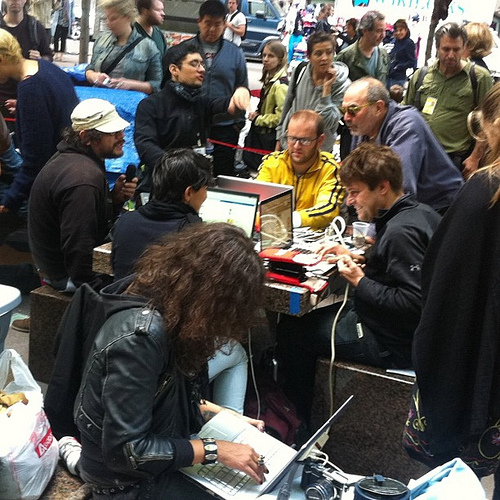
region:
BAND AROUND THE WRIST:
[204, 438, 221, 465]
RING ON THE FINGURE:
[261, 456, 264, 466]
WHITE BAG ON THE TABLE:
[13, 437, 29, 497]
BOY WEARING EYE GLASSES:
[191, 62, 205, 69]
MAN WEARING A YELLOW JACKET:
[308, 177, 333, 200]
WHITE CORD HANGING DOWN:
[336, 294, 343, 351]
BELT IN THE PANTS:
[100, 486, 128, 495]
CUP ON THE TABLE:
[351, 224, 365, 247]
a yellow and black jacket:
[253, 149, 344, 226]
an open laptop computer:
[174, 395, 355, 497]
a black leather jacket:
[78, 272, 194, 481]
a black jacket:
[354, 192, 446, 354]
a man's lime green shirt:
[405, 58, 494, 153]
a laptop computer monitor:
[195, 188, 260, 237]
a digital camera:
[298, 462, 350, 498]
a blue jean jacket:
[88, 29, 163, 93]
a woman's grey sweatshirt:
[274, 61, 349, 151]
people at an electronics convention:
[3, 5, 494, 496]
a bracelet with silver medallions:
[195, 422, 221, 475]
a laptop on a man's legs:
[200, 383, 358, 498]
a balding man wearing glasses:
[269, 94, 341, 217]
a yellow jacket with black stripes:
[266, 157, 346, 231]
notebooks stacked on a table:
[249, 235, 352, 319]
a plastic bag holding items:
[6, 327, 74, 489]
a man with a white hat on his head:
[46, 92, 131, 170]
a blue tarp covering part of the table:
[51, 74, 171, 189]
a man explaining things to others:
[143, 51, 260, 168]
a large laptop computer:
[178, 391, 360, 498]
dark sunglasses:
[337, 103, 370, 118]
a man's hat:
[69, 97, 129, 137]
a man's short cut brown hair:
[333, 140, 410, 195]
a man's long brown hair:
[125, 218, 267, 354]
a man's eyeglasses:
[285, 132, 323, 150]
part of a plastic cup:
[351, 219, 367, 243]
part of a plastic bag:
[0, 346, 67, 498]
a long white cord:
[316, 281, 369, 408]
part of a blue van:
[242, 0, 282, 59]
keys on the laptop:
[217, 471, 243, 484]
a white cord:
[323, 218, 345, 234]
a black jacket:
[381, 228, 411, 260]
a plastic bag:
[5, 428, 45, 484]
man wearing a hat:
[80, 98, 112, 119]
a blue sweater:
[21, 88, 47, 138]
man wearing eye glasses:
[188, 56, 205, 66]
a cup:
[351, 220, 366, 243]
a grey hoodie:
[295, 81, 318, 106]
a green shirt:
[442, 94, 461, 130]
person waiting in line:
[255, 112, 342, 234]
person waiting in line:
[336, 75, 461, 218]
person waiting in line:
[402, 15, 496, 157]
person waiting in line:
[275, 31, 358, 151]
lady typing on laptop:
[33, 220, 353, 499]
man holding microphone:
[16, 93, 163, 253]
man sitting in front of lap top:
[105, 141, 281, 324]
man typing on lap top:
[252, 122, 463, 305]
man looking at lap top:
[322, 65, 480, 222]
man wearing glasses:
[260, 105, 325, 173]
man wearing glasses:
[325, 70, 425, 180]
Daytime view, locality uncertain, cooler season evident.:
[3, 2, 495, 497]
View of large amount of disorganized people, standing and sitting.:
[1, 0, 498, 499]